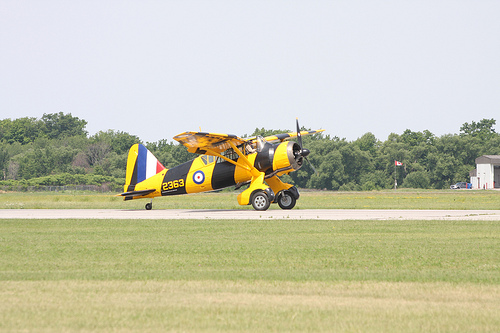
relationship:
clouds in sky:
[78, 50, 219, 84] [7, 8, 497, 122]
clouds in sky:
[0, 0, 500, 134] [1, 0, 500, 137]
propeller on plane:
[291, 120, 310, 170] [105, 117, 327, 213]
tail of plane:
[115, 137, 164, 204] [105, 117, 327, 213]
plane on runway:
[105, 117, 327, 213] [1, 208, 499, 218]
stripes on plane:
[132, 145, 165, 185] [122, 132, 312, 216]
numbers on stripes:
[157, 177, 188, 191] [137, 144, 147, 183]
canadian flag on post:
[391, 159, 401, 166] [392, 161, 398, 186]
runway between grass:
[4, 203, 498, 222] [6, 216, 497, 283]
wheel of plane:
[253, 187, 295, 211] [116, 121, 329, 218]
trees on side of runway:
[1, 110, 499, 192] [0, 207, 497, 222]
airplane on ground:
[111, 115, 326, 214] [0, 218, 500, 333]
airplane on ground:
[111, 115, 325, 214] [3, 185, 498, 256]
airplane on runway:
[111, 115, 325, 214] [5, 206, 483, 220]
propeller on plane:
[295, 116, 303, 154] [105, 117, 327, 213]